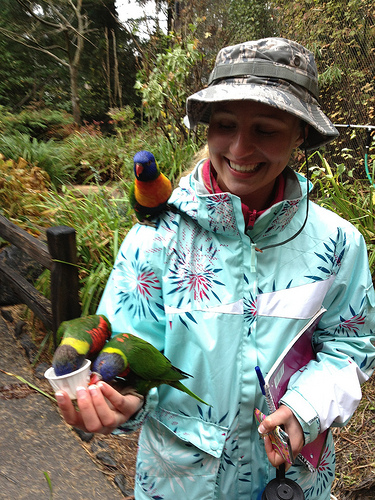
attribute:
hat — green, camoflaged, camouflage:
[180, 35, 341, 153]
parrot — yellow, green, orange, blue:
[129, 150, 174, 229]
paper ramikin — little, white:
[43, 357, 92, 402]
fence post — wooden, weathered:
[46, 224, 82, 342]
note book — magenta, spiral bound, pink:
[264, 307, 329, 473]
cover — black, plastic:
[264, 464, 306, 500]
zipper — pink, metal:
[246, 209, 256, 231]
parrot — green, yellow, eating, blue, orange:
[51, 311, 112, 378]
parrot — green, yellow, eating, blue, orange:
[89, 331, 211, 408]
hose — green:
[364, 155, 375, 186]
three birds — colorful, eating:
[52, 150, 213, 408]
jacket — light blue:
[90, 157, 374, 499]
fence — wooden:
[3, 215, 80, 349]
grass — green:
[3, 131, 374, 317]